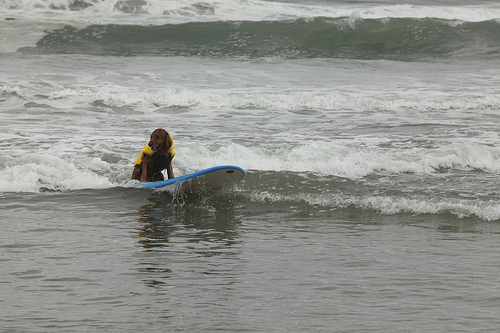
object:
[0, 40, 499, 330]
water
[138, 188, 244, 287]
reflection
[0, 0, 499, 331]
ocean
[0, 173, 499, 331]
shore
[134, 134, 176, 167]
life jacket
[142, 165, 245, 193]
surfboard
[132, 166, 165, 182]
bottom half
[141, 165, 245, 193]
botton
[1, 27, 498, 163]
wave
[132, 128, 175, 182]
surfer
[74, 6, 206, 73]
no object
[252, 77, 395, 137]
no object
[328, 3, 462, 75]
no object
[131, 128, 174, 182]
dog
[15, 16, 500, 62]
ocean wave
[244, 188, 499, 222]
ocean wave